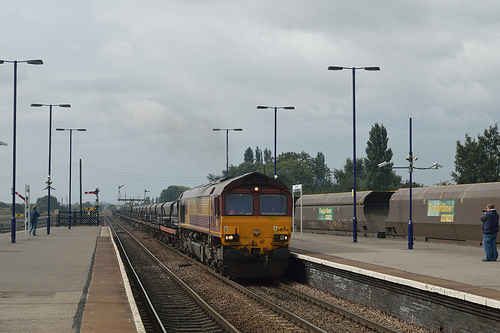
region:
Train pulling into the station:
[132, 175, 281, 281]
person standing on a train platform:
[25, 198, 43, 235]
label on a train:
[416, 189, 463, 226]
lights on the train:
[218, 234, 294, 244]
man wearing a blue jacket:
[476, 204, 499, 230]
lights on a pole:
[20, 54, 45, 73]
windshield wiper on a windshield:
[270, 191, 285, 208]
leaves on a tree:
[363, 117, 388, 189]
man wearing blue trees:
[478, 230, 498, 265]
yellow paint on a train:
[212, 216, 297, 245]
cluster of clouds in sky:
[71, 20, 293, 78]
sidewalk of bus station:
[4, 245, 64, 299]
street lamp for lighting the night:
[328, 61, 377, 241]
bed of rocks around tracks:
[211, 281, 270, 320]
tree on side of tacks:
[453, 124, 499, 178]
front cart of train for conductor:
[173, 173, 293, 277]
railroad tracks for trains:
[261, 283, 328, 315]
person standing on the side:
[23, 202, 38, 234]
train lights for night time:
[223, 233, 291, 244]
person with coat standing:
[481, 201, 498, 259]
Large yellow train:
[107, 169, 297, 277]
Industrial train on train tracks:
[107, 170, 299, 285]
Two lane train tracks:
[102, 207, 397, 332]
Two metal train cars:
[292, 180, 499, 247]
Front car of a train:
[173, 166, 295, 283]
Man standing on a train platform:
[477, 201, 498, 266]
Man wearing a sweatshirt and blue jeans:
[478, 203, 498, 265]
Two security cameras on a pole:
[376, 115, 445, 252]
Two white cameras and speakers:
[374, 149, 444, 171]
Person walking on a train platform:
[26, 198, 42, 235]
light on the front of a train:
[220, 225, 242, 248]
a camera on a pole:
[375, 149, 392, 178]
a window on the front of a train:
[216, 188, 260, 218]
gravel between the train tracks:
[205, 272, 257, 320]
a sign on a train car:
[425, 188, 459, 229]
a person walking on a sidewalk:
[29, 194, 46, 241]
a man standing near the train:
[469, 189, 498, 264]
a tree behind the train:
[351, 134, 398, 191]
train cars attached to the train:
[128, 188, 185, 240]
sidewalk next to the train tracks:
[22, 247, 111, 317]